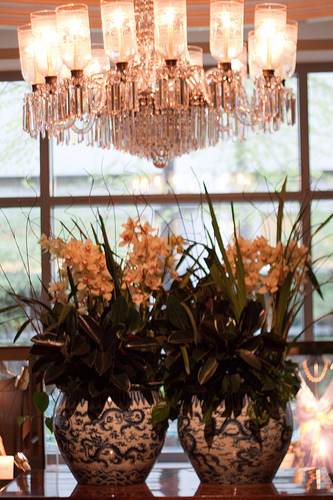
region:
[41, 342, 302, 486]
Two vases on a table.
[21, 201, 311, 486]
Two vases full of flowers.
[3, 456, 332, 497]
Brown wooden table.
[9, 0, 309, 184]
Chandelier hanging from ceiling.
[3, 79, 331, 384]
Photo taken during the day.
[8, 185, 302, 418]
Flowers in vases.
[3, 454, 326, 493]
Reflection of light on table.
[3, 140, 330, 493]
No people pictured.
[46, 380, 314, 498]
White vases with blue designs.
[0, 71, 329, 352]
Window behind the flowers.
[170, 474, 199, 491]
surface of a furniture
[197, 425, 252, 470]
surface of a vase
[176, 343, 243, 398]
leaves of a plant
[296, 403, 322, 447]
part of a shiny decor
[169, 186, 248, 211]
part of a window boundary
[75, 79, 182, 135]
part of a bulb guard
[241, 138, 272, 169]
part of a window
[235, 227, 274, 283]
part of some flowers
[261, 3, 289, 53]
part of a light bulb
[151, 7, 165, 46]
light on the bulb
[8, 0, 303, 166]
crystal and glass chandelier hanging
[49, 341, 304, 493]
blue and white pottery planter pots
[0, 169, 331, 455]
green leaves with large white flowers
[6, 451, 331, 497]
shiny wooden table under pots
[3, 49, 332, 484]
brown wooden framed window scene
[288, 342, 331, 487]
black mannequin reflected in window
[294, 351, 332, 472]
mannequin with white dress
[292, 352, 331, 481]
mannequin with white pearls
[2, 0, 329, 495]
this is an indoor daytime room scene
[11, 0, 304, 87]
lighted glass flutes on crystal drop chandelier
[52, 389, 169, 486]
blue and white large porcelain vase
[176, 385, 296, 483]
blue and white large porcelain vase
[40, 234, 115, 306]
small white and pink flowers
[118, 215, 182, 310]
small white and pink flowers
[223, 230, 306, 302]
small white and pink flowers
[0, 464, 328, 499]
smooth wooden shiny table top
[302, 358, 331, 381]
reflection of a necklace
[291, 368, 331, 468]
reflection of a dress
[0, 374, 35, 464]
dress hanging in the window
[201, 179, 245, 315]
long green leaf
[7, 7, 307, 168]
chandelier composed of pendants and candles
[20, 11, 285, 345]
lighting fixture hanging over flowers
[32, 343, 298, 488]
blue vases filled with orchids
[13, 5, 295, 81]
bright light within glass shade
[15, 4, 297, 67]
glass shades surrounding crystals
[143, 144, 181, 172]
round crystal at bottom of chandelier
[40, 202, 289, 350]
tall and spiky leaves in flower arrangement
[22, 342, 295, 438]
leaves hanging over vases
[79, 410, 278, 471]
blue dragons across white vases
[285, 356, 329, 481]
necklace and dress on hanger